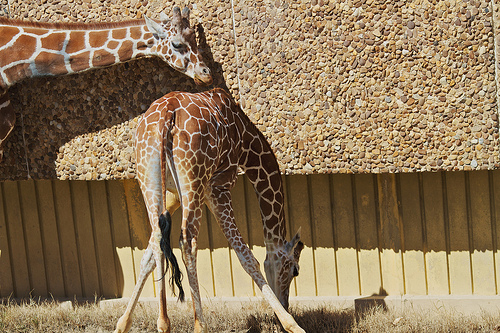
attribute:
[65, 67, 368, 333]
giraffe — young, brown, blowing, large, baby, leaning, larger, wall, small, mother, eating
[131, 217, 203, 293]
hair — black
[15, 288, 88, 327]
grass — dry, dried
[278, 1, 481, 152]
wall — brown, rock, wood, top, tan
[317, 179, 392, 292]
wood — slat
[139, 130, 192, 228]
tail — skinny